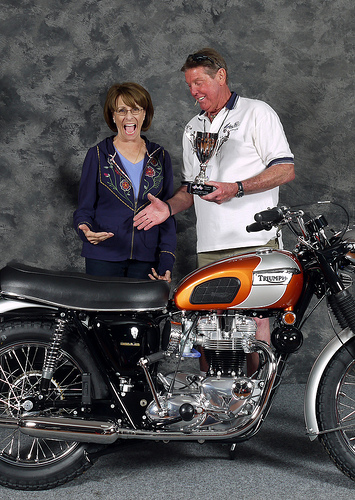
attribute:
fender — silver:
[302, 336, 344, 418]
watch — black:
[234, 173, 246, 199]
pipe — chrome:
[0, 323, 286, 443]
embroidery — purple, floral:
[94, 147, 169, 222]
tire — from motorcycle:
[311, 329, 354, 476]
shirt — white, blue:
[181, 91, 297, 253]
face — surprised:
[186, 65, 220, 108]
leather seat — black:
[0, 259, 167, 309]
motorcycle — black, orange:
[2, 202, 354, 492]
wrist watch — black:
[232, 182, 248, 200]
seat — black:
[1, 260, 168, 311]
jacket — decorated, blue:
[76, 144, 176, 278]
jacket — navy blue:
[80, 135, 193, 277]